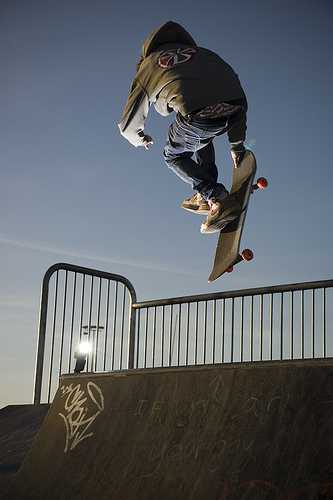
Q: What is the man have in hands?
A: A skateboard.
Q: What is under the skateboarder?
A: Skateboard.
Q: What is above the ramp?
A: A fence.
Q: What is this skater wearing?
A: A sweatshirt with the hood.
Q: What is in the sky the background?
A: White cloud.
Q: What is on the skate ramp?
A: A lots of words.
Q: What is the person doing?
A: Riding a skateboard in the air.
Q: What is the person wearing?
A: A hooded sweatshirt.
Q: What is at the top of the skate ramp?
A: A metal fence.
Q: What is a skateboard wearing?
A: Blue jeans.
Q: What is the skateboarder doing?
A: A midair trick.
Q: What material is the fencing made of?
A: Metal.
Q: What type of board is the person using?
A: A skateboard.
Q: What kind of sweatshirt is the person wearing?
A: A hoodie.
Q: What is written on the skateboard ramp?
A: Graffiti.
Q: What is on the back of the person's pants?
A: Pockets.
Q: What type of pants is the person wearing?
A: Blue Jeans.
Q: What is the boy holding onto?
A: A skateboard.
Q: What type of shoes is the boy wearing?
A: Skating shoes.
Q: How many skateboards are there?
A: One.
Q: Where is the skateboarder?
A: In the air.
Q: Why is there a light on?
A: It is getting dark.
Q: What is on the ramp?
A: Graffiti.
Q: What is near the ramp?
A: A fence.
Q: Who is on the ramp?
A: A skateboarder.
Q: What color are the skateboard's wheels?
A: Red.